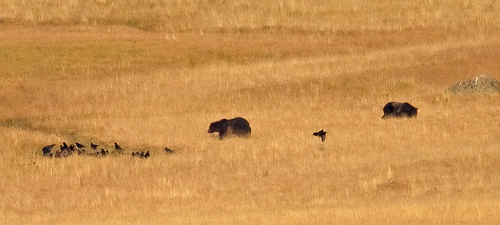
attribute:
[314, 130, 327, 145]
bird — flying away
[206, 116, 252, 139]
bear — brown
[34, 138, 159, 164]
birds — black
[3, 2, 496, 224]
grass — dry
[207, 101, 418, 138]
bears — black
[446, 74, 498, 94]
pile — small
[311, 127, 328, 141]
bird — flying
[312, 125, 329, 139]
bird — black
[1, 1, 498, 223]
weeds — tall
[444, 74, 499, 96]
rock — low, laying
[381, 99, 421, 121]
bear — brown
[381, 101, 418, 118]
bear — black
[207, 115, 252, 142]
bear — black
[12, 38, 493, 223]
grass — gold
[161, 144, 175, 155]
birds — black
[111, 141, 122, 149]
birds — black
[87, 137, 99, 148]
birds — black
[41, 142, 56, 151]
birds — black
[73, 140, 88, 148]
birds — black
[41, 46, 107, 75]
greener grass — flat-lying, green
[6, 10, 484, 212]
pasture — dry, grass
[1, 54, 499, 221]
field — large